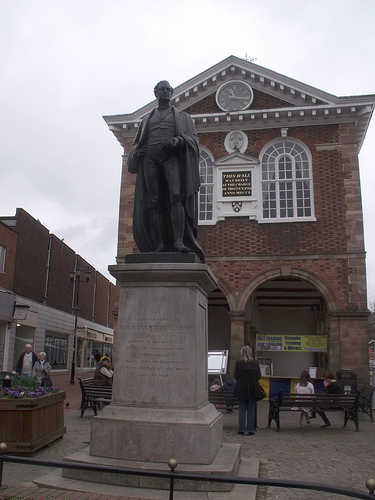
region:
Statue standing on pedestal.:
[109, 73, 218, 289]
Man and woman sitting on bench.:
[284, 364, 352, 437]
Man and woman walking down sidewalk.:
[12, 335, 57, 388]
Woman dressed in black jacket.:
[227, 358, 266, 399]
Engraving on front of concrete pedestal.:
[116, 309, 204, 413]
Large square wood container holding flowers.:
[1, 374, 67, 456]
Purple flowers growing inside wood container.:
[2, 375, 60, 402]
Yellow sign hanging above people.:
[252, 324, 333, 356]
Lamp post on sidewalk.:
[66, 252, 92, 388]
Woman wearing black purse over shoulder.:
[250, 370, 267, 402]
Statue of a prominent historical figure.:
[100, 71, 217, 295]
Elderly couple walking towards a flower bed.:
[8, 335, 61, 386]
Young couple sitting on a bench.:
[278, 360, 357, 423]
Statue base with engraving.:
[95, 293, 224, 407]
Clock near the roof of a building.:
[189, 75, 280, 112]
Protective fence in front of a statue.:
[0, 428, 374, 487]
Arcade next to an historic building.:
[7, 208, 112, 404]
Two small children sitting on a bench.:
[210, 371, 237, 407]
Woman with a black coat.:
[232, 341, 263, 434]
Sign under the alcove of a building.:
[250, 326, 332, 356]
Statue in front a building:
[94, 72, 218, 263]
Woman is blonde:
[227, 335, 271, 439]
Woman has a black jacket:
[225, 336, 272, 443]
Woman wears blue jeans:
[230, 339, 270, 439]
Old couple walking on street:
[7, 337, 58, 394]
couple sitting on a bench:
[268, 365, 367, 432]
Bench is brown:
[260, 386, 364, 435]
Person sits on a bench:
[88, 349, 116, 391]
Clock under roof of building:
[211, 74, 258, 115]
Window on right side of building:
[253, 131, 321, 227]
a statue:
[110, 59, 253, 298]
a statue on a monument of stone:
[87, 69, 239, 460]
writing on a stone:
[102, 274, 234, 421]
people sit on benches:
[80, 341, 371, 431]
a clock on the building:
[175, 58, 358, 137]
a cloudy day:
[35, 15, 336, 314]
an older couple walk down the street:
[13, 335, 65, 411]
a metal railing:
[13, 431, 359, 498]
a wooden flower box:
[4, 368, 76, 461]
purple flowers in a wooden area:
[1, 363, 94, 453]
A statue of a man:
[125, 79, 200, 266]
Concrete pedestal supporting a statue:
[32, 260, 261, 497]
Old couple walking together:
[10, 342, 52, 389]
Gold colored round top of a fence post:
[165, 457, 178, 468]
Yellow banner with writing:
[252, 332, 328, 352]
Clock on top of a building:
[214, 78, 254, 111]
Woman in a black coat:
[233, 346, 265, 435]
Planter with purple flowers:
[1, 372, 66, 455]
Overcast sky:
[0, 2, 373, 313]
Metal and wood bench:
[265, 387, 361, 433]